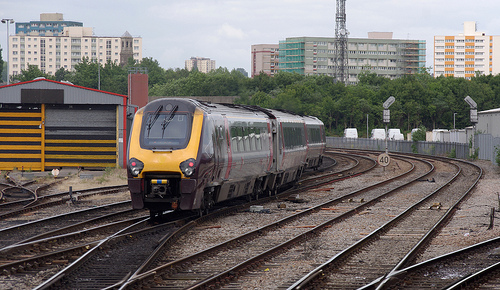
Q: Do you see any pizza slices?
A: No, there are no pizza slices.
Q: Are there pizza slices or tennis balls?
A: No, there are no pizza slices or tennis balls.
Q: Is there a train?
A: Yes, there is a train.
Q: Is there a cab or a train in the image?
A: Yes, there is a train.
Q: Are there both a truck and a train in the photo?
A: No, there is a train but no trucks.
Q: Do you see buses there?
A: No, there are no buses.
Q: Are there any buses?
A: No, there are no buses.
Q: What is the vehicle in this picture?
A: The vehicle is a train.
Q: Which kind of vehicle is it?
A: The vehicle is a train.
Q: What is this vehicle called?
A: This is a train.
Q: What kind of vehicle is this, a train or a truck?
A: This is a train.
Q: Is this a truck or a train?
A: This is a train.